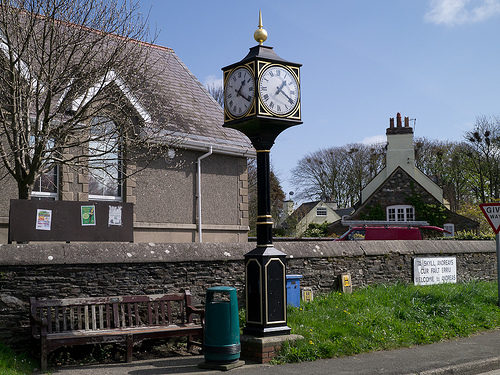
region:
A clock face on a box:
[222, 67, 255, 116]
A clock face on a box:
[256, 60, 298, 118]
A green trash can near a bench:
[201, 285, 241, 362]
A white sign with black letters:
[410, 255, 457, 285]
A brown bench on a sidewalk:
[22, 293, 209, 364]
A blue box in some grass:
[280, 273, 304, 311]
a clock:
[258, 62, 305, 115]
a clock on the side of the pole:
[221, 67, 258, 111]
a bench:
[26, 293, 196, 334]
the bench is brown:
[33, 295, 190, 332]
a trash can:
[204, 286, 246, 351]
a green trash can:
[199, 288, 242, 348]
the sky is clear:
[339, 40, 396, 79]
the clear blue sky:
[318, 79, 376, 116]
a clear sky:
[311, 48, 374, 90]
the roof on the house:
[171, 75, 206, 107]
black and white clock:
[248, 51, 293, 126]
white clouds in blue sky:
[345, 35, 372, 69]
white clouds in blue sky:
[443, 15, 481, 53]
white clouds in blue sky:
[390, 21, 438, 82]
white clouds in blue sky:
[340, 55, 361, 90]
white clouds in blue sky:
[202, 22, 232, 39]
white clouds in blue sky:
[319, 32, 364, 72]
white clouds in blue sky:
[322, 89, 347, 104]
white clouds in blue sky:
[363, 38, 388, 56]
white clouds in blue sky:
[423, 39, 467, 71]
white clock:
[225, 38, 286, 123]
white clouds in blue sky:
[344, 21, 378, 49]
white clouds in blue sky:
[444, 31, 481, 62]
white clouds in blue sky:
[315, 99, 349, 129]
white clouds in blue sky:
[437, 83, 471, 114]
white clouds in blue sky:
[402, 63, 472, 114]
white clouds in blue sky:
[331, 9, 389, 39]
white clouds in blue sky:
[160, 5, 217, 36]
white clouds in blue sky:
[327, 59, 361, 96]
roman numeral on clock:
[272, 68, 283, 75]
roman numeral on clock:
[281, 72, 288, 79]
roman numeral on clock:
[286, 79, 294, 86]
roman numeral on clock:
[274, 103, 282, 112]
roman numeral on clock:
[266, 100, 275, 112]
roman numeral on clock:
[261, 91, 270, 104]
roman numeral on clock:
[259, 84, 269, 92]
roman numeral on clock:
[262, 74, 270, 82]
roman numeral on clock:
[236, 70, 244, 79]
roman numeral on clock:
[227, 80, 234, 90]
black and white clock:
[223, 33, 298, 115]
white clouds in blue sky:
[325, 28, 356, 60]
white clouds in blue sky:
[399, 39, 444, 63]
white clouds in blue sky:
[419, 5, 456, 26]